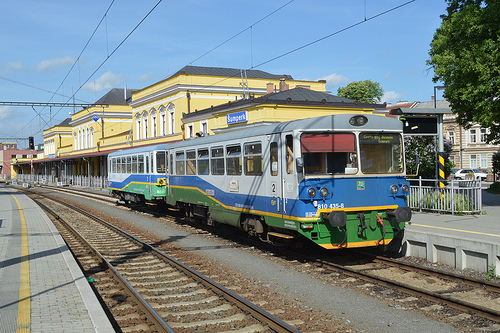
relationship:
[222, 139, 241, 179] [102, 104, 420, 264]
window of train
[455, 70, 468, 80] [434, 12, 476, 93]
leaves on tree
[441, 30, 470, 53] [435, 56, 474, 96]
leaves on tree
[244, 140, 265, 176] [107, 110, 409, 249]
window on train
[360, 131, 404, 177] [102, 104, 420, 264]
window on train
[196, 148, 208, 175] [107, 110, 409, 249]
window on train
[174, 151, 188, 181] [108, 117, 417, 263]
window on train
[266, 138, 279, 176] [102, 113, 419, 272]
window on train